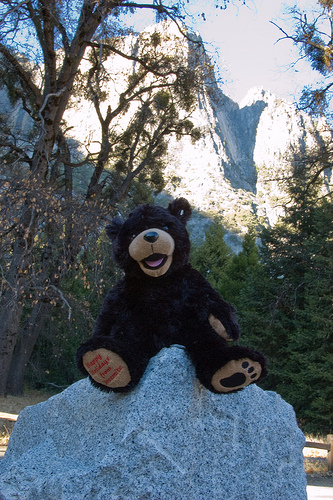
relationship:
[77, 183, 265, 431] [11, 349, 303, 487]
bear on rock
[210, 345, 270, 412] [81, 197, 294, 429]
paw on bear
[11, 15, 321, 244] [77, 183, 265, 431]
mountains behind bear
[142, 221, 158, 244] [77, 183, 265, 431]
nose on bear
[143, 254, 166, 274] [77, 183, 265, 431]
tongue on bear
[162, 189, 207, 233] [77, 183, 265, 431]
ear on bear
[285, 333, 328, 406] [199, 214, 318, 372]
leaf on tree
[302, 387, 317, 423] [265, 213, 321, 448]
leaf on tree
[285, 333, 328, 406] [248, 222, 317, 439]
leaf on tree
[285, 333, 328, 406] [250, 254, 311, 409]
leaf on tree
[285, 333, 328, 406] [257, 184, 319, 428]
leaf on tree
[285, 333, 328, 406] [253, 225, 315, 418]
leaf on tree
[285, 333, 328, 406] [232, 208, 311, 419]
leaf on tree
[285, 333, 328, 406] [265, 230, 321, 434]
leaf on tree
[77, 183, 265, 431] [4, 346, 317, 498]
bear on rock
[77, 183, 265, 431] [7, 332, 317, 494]
bear on rock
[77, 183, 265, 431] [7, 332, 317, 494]
bear sitting on rock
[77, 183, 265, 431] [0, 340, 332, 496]
bear sitting on rock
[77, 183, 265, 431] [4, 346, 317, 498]
bear sitting on rock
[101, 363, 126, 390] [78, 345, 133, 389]
word on sole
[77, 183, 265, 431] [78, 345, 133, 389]
bear has sole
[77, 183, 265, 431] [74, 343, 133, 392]
bear has sole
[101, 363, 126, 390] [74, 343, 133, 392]
word on sole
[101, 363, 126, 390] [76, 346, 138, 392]
word on sole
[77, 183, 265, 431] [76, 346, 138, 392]
bear has sole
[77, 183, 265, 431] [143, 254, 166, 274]
bear has tongue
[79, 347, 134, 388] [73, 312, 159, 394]
bottom of leg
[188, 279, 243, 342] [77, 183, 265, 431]
arm of bear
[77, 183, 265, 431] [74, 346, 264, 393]
bear with paws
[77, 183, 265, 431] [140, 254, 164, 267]
bear with tongue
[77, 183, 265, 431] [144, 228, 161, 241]
bear with nose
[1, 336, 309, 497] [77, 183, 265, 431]
boulder under bear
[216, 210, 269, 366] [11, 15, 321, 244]
tree in front of mountains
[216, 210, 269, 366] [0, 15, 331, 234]
tree in front of mountains